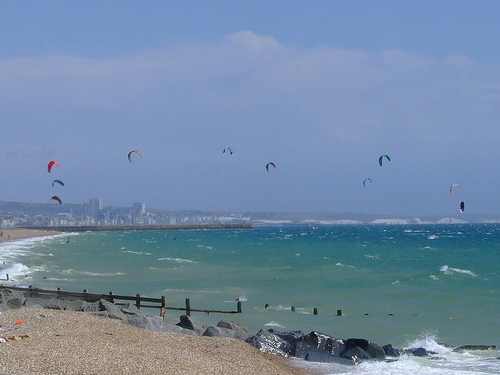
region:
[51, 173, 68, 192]
blue kite in the sky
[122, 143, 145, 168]
orange kite in the sky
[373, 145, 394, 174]
green kite in the sky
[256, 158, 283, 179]
rainbow kite in the sky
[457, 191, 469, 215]
black kite in the sky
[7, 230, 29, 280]
waves washing ashore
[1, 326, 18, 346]
person laying in the sand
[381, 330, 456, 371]
waves crashing on rocks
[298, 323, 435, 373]
waves crashing on rocks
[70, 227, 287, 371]
water near a beach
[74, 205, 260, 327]
water near a beach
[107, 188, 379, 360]
water near a beach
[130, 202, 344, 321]
water near a beach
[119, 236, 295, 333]
water near a beach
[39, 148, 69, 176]
kite in the sky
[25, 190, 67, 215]
kite in the sky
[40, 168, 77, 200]
kite in the sky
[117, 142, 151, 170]
kite in the sky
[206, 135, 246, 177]
kite in the sky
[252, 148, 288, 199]
kite in the sky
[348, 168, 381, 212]
kite in the sky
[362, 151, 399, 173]
kite in the sky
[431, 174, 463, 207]
kite in the sky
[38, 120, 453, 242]
a group of parachuates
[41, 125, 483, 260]
a large group of parachuates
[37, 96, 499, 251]
a wide group of parachuates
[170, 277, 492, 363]
people in the water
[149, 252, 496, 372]
people near the water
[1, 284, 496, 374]
Large gray rocks along shore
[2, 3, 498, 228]
Ten kites flying in the sky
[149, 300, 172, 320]
Person standing in the water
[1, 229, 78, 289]
White waves crashing on sand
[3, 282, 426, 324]
Line of wood posts going in to water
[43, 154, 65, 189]
Red and blue kites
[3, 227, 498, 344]
Ocean with many big waves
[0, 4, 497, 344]
Kites flying over the blue ocean